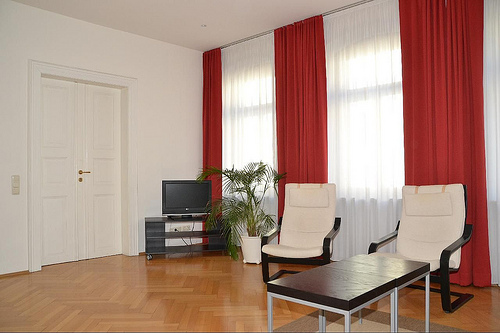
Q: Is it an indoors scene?
A: Yes, it is indoors.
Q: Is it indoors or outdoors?
A: It is indoors.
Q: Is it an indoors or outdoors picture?
A: It is indoors.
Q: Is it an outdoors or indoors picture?
A: It is indoors.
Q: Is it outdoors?
A: No, it is indoors.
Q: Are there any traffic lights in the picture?
A: No, there are no traffic lights.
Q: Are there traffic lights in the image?
A: No, there are no traffic lights.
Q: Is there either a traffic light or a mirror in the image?
A: No, there are no traffic lights or mirrors.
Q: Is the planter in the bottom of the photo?
A: Yes, the planter is in the bottom of the image.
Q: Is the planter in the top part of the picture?
A: No, the planter is in the bottom of the image.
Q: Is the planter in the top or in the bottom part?
A: The planter is in the bottom of the image.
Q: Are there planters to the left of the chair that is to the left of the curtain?
A: Yes, there is a planter to the left of the chair.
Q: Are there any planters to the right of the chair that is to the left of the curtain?
A: No, the planter is to the left of the chair.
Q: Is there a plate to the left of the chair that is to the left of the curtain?
A: No, there is a planter to the left of the chair.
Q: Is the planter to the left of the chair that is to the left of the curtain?
A: Yes, the planter is to the left of the chair.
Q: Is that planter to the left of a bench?
A: No, the planter is to the left of the chair.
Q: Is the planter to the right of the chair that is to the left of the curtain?
A: No, the planter is to the left of the chair.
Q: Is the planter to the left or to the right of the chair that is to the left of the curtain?
A: The planter is to the left of the chair.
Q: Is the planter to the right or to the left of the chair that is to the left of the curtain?
A: The planter is to the left of the chair.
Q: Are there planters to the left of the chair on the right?
A: Yes, there is a planter to the left of the chair.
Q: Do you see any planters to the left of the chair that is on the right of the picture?
A: Yes, there is a planter to the left of the chair.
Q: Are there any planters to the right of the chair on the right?
A: No, the planter is to the left of the chair.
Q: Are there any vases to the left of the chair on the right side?
A: No, there is a planter to the left of the chair.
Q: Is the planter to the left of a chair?
A: Yes, the planter is to the left of a chair.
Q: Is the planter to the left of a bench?
A: No, the planter is to the left of a chair.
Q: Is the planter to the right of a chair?
A: No, the planter is to the left of a chair.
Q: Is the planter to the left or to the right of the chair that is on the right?
A: The planter is to the left of the chair.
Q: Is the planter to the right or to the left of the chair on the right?
A: The planter is to the left of the chair.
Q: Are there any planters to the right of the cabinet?
A: Yes, there is a planter to the right of the cabinet.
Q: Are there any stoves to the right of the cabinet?
A: No, there is a planter to the right of the cabinet.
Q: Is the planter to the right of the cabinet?
A: Yes, the planter is to the right of the cabinet.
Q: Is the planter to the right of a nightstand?
A: No, the planter is to the right of the cabinet.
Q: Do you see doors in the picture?
A: Yes, there are doors.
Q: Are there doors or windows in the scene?
A: Yes, there are doors.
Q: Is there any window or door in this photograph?
A: Yes, there are doors.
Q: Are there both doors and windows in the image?
A: Yes, there are both doors and a window.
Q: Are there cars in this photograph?
A: No, there are no cars.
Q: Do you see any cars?
A: No, there are no cars.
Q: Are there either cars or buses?
A: No, there are no cars or buses.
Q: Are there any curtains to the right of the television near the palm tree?
A: Yes, there are curtains to the right of the television.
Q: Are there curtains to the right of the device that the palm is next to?
A: Yes, there are curtains to the right of the television.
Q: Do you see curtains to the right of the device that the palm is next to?
A: Yes, there are curtains to the right of the television.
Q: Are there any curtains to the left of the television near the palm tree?
A: No, the curtains are to the right of the television.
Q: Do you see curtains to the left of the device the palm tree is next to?
A: No, the curtains are to the right of the television.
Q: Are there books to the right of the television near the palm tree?
A: No, there are curtains to the right of the television.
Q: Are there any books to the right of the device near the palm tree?
A: No, there are curtains to the right of the television.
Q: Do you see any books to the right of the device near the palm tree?
A: No, there are curtains to the right of the television.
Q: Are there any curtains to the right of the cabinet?
A: Yes, there are curtains to the right of the cabinet.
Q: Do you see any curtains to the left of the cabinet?
A: No, the curtains are to the right of the cabinet.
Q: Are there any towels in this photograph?
A: No, there are no towels.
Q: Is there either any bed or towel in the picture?
A: No, there are no towels or beds.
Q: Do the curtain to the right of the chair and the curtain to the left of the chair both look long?
A: Yes, both the curtain and the curtain are long.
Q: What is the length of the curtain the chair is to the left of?
A: The curtain is long.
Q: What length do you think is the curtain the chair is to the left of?
A: The curtain is long.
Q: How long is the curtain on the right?
A: The curtain is long.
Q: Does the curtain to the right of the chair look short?
A: No, the curtain is long.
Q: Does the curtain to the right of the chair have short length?
A: No, the curtain is long.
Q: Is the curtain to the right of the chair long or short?
A: The curtain is long.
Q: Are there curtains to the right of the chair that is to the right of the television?
A: Yes, there is a curtain to the right of the chair.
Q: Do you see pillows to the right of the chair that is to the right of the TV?
A: No, there is a curtain to the right of the chair.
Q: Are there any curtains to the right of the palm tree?
A: Yes, there is a curtain to the right of the palm tree.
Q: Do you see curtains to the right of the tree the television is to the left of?
A: Yes, there is a curtain to the right of the palm tree.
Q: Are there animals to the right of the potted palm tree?
A: No, there is a curtain to the right of the palm.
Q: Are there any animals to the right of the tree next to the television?
A: No, there is a curtain to the right of the palm.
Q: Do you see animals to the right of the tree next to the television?
A: No, there is a curtain to the right of the palm.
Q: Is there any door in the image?
A: Yes, there are doors.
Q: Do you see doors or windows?
A: Yes, there are doors.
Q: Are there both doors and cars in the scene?
A: No, there are doors but no cars.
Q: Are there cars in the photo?
A: No, there are no cars.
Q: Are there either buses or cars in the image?
A: No, there are no cars or buses.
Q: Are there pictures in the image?
A: No, there are no pictures.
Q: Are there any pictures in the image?
A: No, there are no pictures.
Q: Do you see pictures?
A: No, there are no pictures.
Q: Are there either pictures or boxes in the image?
A: No, there are no pictures or boxes.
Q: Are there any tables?
A: Yes, there is a table.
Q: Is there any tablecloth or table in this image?
A: Yes, there is a table.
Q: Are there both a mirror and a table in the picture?
A: No, there is a table but no mirrors.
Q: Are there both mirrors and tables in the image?
A: No, there is a table but no mirrors.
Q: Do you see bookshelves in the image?
A: No, there are no bookshelves.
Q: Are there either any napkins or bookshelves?
A: No, there are no bookshelves or napkins.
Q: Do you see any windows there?
A: Yes, there is a window.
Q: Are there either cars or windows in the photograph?
A: Yes, there is a window.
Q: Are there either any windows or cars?
A: Yes, there is a window.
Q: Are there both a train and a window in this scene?
A: No, there is a window but no trains.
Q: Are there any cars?
A: No, there are no cars.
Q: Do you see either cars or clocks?
A: No, there are no cars or clocks.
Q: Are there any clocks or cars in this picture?
A: No, there are no cars or clocks.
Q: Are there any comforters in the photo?
A: No, there are no comforters.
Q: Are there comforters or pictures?
A: No, there are no comforters or pictures.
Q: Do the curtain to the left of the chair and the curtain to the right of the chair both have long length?
A: Yes, both the curtain and the curtain are long.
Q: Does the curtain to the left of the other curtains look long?
A: Yes, the curtain is long.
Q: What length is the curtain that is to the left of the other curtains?
A: The curtain is long.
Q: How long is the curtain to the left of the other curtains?
A: The curtain is long.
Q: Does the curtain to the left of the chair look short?
A: No, the curtain is long.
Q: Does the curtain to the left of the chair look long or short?
A: The curtain is long.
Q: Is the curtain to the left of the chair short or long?
A: The curtain is long.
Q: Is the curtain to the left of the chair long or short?
A: The curtain is long.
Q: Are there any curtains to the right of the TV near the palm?
A: Yes, there is a curtain to the right of the TV.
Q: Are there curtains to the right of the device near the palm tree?
A: Yes, there is a curtain to the right of the TV.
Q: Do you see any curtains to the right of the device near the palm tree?
A: Yes, there is a curtain to the right of the TV.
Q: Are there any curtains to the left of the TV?
A: No, the curtain is to the right of the TV.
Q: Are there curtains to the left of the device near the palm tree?
A: No, the curtain is to the right of the TV.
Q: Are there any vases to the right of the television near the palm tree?
A: No, there is a curtain to the right of the television.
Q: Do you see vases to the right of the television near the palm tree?
A: No, there is a curtain to the right of the television.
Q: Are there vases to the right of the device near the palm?
A: No, there is a curtain to the right of the television.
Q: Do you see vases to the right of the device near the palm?
A: No, there is a curtain to the right of the television.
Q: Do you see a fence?
A: No, there are no fences.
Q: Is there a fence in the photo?
A: No, there are no fences.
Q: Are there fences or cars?
A: No, there are no fences or cars.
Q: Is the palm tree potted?
A: Yes, the palm tree is potted.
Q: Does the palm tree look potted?
A: Yes, the palm tree is potted.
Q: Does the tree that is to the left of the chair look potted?
A: Yes, the palm tree is potted.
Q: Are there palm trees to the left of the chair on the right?
A: Yes, there is a palm tree to the left of the chair.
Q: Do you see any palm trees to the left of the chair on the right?
A: Yes, there is a palm tree to the left of the chair.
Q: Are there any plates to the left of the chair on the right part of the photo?
A: No, there is a palm tree to the left of the chair.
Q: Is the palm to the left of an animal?
A: No, the palm is to the left of a chair.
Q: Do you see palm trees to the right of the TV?
A: Yes, there is a palm tree to the right of the TV.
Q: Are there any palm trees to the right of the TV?
A: Yes, there is a palm tree to the right of the TV.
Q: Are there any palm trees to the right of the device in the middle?
A: Yes, there is a palm tree to the right of the TV.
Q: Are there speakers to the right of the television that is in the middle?
A: No, there is a palm tree to the right of the TV.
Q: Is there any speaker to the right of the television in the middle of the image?
A: No, there is a palm tree to the right of the TV.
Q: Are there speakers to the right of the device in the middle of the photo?
A: No, there is a palm tree to the right of the TV.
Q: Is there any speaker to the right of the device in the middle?
A: No, there is a palm tree to the right of the TV.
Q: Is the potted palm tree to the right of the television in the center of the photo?
A: Yes, the palm is to the right of the TV.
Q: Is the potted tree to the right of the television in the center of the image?
A: Yes, the palm is to the right of the TV.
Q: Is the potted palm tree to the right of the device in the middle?
A: Yes, the palm is to the right of the TV.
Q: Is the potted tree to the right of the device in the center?
A: Yes, the palm is to the right of the TV.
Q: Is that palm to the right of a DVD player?
A: No, the palm is to the right of the TV.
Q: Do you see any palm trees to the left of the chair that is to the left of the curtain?
A: Yes, there is a palm tree to the left of the chair.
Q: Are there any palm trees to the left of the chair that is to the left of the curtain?
A: Yes, there is a palm tree to the left of the chair.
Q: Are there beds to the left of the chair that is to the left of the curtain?
A: No, there is a palm tree to the left of the chair.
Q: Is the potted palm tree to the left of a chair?
A: Yes, the palm tree is to the left of a chair.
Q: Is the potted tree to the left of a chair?
A: Yes, the palm tree is to the left of a chair.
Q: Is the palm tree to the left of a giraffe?
A: No, the palm tree is to the left of a chair.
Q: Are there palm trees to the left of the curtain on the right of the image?
A: Yes, there is a palm tree to the left of the curtain.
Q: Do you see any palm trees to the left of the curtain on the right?
A: Yes, there is a palm tree to the left of the curtain.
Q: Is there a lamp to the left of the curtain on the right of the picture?
A: No, there is a palm tree to the left of the curtain.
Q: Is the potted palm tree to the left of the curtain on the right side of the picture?
A: Yes, the palm tree is to the left of the curtain.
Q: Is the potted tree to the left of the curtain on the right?
A: Yes, the palm tree is to the left of the curtain.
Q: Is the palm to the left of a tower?
A: No, the palm is to the left of the curtain.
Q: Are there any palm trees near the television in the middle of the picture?
A: Yes, there is a palm tree near the TV.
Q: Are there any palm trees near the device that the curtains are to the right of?
A: Yes, there is a palm tree near the TV.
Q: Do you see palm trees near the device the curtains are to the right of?
A: Yes, there is a palm tree near the TV.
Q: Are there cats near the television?
A: No, there is a palm tree near the television.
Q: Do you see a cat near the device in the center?
A: No, there is a palm tree near the television.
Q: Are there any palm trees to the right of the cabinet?
A: Yes, there is a palm tree to the right of the cabinet.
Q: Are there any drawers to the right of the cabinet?
A: No, there is a palm tree to the right of the cabinet.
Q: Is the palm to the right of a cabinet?
A: Yes, the palm is to the right of a cabinet.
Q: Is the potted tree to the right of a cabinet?
A: Yes, the palm is to the right of a cabinet.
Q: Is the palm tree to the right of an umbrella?
A: No, the palm tree is to the right of a cabinet.